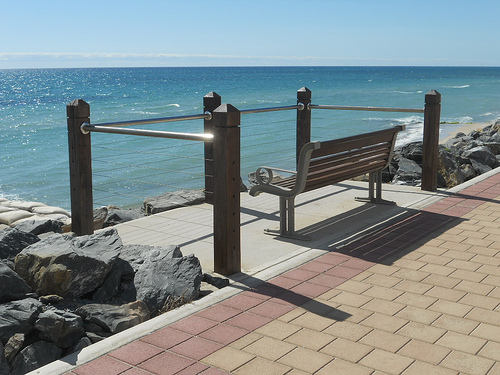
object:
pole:
[203, 91, 223, 203]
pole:
[295, 87, 314, 171]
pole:
[421, 88, 442, 192]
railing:
[66, 85, 442, 274]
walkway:
[0, 167, 500, 375]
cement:
[99, 177, 436, 293]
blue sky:
[0, 0, 500, 69]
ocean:
[0, 65, 499, 203]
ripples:
[0, 67, 201, 155]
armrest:
[255, 166, 298, 192]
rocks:
[140, 187, 206, 218]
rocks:
[0, 199, 231, 375]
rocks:
[386, 118, 499, 190]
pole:
[67, 98, 94, 237]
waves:
[442, 82, 471, 87]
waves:
[122, 94, 186, 116]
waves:
[362, 111, 425, 148]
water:
[0, 65, 500, 214]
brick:
[47, 175, 500, 375]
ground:
[1, 166, 500, 375]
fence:
[67, 86, 441, 276]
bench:
[247, 123, 407, 242]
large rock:
[14, 226, 124, 300]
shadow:
[259, 193, 471, 267]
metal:
[79, 122, 215, 143]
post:
[212, 103, 243, 278]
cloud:
[0, 46, 391, 65]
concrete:
[95, 177, 443, 296]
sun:
[196, 131, 214, 144]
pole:
[212, 101, 242, 278]